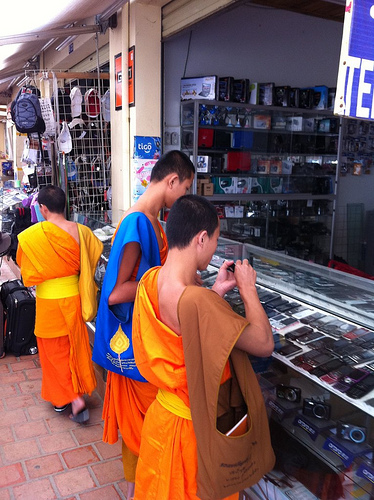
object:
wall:
[109, 3, 165, 226]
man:
[130, 193, 274, 499]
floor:
[0, 255, 139, 499]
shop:
[135, 0, 373, 499]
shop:
[2, 22, 121, 357]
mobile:
[283, 324, 312, 340]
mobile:
[295, 330, 328, 346]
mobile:
[272, 316, 298, 329]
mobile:
[301, 347, 337, 372]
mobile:
[272, 338, 292, 352]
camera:
[302, 391, 331, 420]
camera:
[275, 380, 302, 404]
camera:
[335, 417, 366, 446]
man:
[103, 149, 196, 500]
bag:
[76, 223, 104, 321]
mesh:
[22, 69, 114, 227]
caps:
[69, 86, 83, 118]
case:
[180, 100, 344, 263]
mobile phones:
[311, 314, 335, 329]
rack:
[29, 62, 113, 253]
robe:
[100, 213, 170, 456]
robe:
[131, 265, 232, 498]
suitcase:
[0, 273, 41, 357]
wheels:
[28, 345, 38, 356]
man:
[14, 187, 101, 424]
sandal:
[71, 408, 90, 423]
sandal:
[53, 403, 69, 412]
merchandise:
[9, 75, 112, 226]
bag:
[176, 283, 276, 497]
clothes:
[15, 220, 103, 409]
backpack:
[10, 82, 46, 135]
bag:
[90, 210, 160, 384]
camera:
[222, 258, 236, 273]